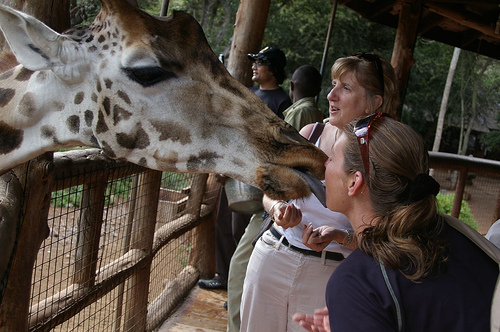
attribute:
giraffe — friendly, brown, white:
[2, 1, 327, 203]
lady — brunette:
[293, 111, 498, 331]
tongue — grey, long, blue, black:
[296, 169, 328, 208]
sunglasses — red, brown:
[354, 112, 388, 187]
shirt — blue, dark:
[326, 219, 498, 331]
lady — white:
[238, 50, 395, 331]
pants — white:
[240, 223, 347, 331]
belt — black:
[267, 224, 345, 263]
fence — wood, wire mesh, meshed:
[2, 147, 223, 332]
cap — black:
[248, 44, 288, 69]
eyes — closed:
[326, 152, 337, 165]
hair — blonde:
[345, 116, 450, 287]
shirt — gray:
[253, 89, 294, 121]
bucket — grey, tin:
[223, 176, 268, 213]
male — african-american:
[226, 66, 319, 331]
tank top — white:
[274, 120, 359, 255]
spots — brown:
[1, 15, 217, 177]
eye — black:
[120, 62, 177, 89]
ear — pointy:
[1, 3, 67, 74]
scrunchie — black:
[409, 171, 442, 201]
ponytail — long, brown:
[356, 183, 451, 284]